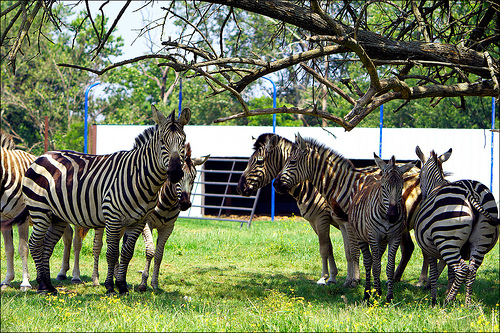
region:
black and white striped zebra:
[23, 98, 196, 295]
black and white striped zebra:
[0, 123, 62, 301]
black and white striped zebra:
[400, 135, 495, 310]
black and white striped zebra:
[340, 151, 422, 293]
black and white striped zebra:
[276, 126, 427, 289]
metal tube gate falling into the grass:
[154, 148, 279, 235]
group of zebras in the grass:
[240, 128, 497, 307]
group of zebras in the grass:
[0, 104, 226, 306]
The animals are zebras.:
[1, 40, 498, 274]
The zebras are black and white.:
[29, 126, 193, 241]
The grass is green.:
[194, 243, 288, 319]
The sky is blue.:
[82, 1, 172, 62]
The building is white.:
[88, 107, 498, 186]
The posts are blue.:
[248, 72, 291, 234]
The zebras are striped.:
[241, 97, 469, 282]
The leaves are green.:
[102, 55, 244, 117]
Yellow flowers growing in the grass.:
[250, 277, 309, 325]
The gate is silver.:
[167, 134, 260, 235]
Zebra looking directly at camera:
[121, 102, 207, 190]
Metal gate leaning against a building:
[189, 149, 257, 227]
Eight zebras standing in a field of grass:
[1, 126, 498, 305]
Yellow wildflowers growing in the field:
[251, 288, 311, 330]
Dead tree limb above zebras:
[121, 35, 496, 107]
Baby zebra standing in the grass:
[350, 148, 417, 300]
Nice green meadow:
[190, 217, 290, 318]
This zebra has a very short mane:
[273, 134, 345, 208]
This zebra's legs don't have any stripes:
[2, 227, 36, 293]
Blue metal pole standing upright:
[483, 95, 497, 180]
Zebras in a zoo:
[1, 102, 498, 312]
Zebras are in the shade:
[232, 121, 499, 315]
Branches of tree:
[0, 0, 495, 120]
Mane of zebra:
[303, 134, 358, 172]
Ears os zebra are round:
[144, 100, 195, 131]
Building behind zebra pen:
[73, 108, 497, 155]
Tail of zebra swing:
[463, 191, 498, 233]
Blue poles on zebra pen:
[73, 67, 499, 121]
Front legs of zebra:
[96, 213, 141, 306]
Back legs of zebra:
[18, 216, 70, 301]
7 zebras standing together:
[7, 81, 490, 307]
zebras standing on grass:
[22, 45, 485, 298]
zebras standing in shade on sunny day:
[23, 34, 460, 302]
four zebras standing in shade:
[236, 96, 488, 313]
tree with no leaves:
[118, 28, 487, 119]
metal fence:
[183, 150, 266, 234]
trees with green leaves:
[9, 37, 79, 141]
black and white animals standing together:
[22, 78, 483, 291]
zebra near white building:
[68, 88, 484, 220]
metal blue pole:
[68, 80, 110, 147]